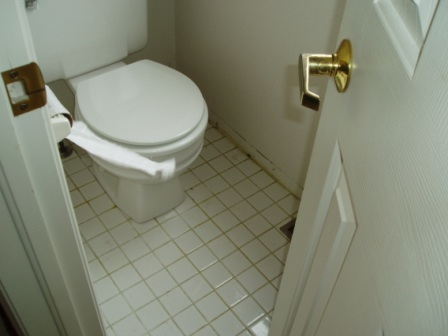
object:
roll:
[42, 83, 74, 141]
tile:
[171, 304, 208, 336]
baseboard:
[208, 116, 302, 199]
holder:
[49, 112, 72, 144]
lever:
[24, 0, 37, 7]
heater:
[279, 211, 299, 242]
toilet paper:
[62, 121, 176, 176]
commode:
[73, 59, 211, 225]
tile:
[213, 276, 249, 310]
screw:
[19, 104, 27, 109]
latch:
[0, 61, 47, 117]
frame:
[0, 1, 104, 336]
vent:
[279, 218, 297, 242]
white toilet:
[25, 2, 211, 224]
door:
[269, 1, 446, 335]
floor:
[58, 118, 303, 336]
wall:
[171, 0, 341, 202]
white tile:
[177, 228, 201, 256]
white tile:
[220, 251, 252, 276]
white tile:
[179, 273, 213, 303]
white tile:
[130, 253, 164, 279]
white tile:
[210, 308, 246, 335]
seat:
[73, 59, 210, 225]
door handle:
[295, 36, 351, 112]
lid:
[74, 58, 206, 148]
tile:
[225, 222, 255, 246]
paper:
[63, 119, 176, 180]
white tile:
[183, 244, 220, 271]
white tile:
[231, 176, 262, 199]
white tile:
[211, 276, 250, 304]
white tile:
[223, 221, 255, 250]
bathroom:
[0, 0, 448, 336]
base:
[115, 178, 186, 223]